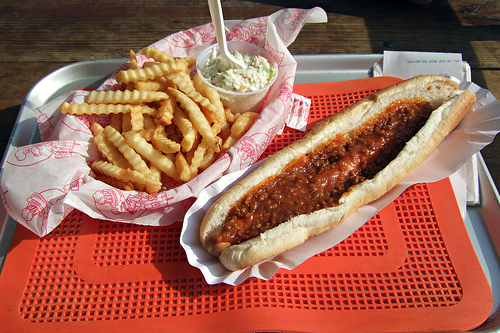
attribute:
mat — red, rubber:
[2, 67, 492, 325]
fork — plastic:
[205, 0, 245, 72]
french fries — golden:
[76, 47, 254, 184]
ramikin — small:
[193, 37, 280, 112]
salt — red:
[278, 72, 327, 145]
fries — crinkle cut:
[60, 37, 260, 212]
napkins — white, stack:
[388, 44, 485, 210]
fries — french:
[111, 52, 267, 157]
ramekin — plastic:
[193, 38, 279, 113]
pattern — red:
[166, 20, 215, 47]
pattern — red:
[7, 141, 79, 165]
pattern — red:
[237, 125, 282, 167]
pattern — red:
[91, 187, 175, 220]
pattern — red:
[22, 177, 87, 233]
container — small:
[195, 38, 277, 112]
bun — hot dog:
[196, 73, 477, 270]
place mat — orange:
[351, 241, 460, 305]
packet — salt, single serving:
[265, 87, 349, 147]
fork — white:
[203, 0, 244, 67]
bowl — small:
[190, 43, 305, 129]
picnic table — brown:
[9, 7, 499, 247]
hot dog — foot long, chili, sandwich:
[210, 112, 450, 259]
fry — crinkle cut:
[86, 89, 163, 101]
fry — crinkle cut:
[61, 101, 153, 113]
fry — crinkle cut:
[150, 131, 182, 153]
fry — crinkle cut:
[106, 128, 148, 171]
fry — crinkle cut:
[90, 159, 133, 179]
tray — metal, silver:
[0, 51, 498, 329]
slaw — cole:
[203, 35, 276, 106]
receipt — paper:
[377, 42, 487, 210]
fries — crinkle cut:
[59, 45, 256, 199]